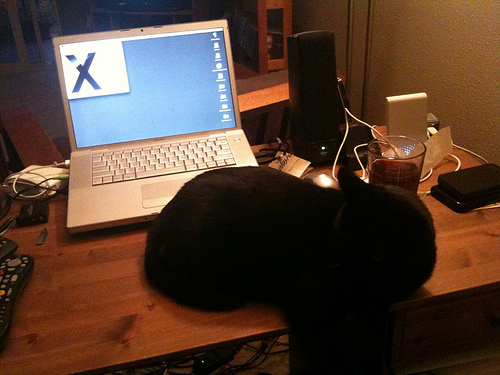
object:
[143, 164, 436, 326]
cat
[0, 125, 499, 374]
desk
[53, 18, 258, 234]
computer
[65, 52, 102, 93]
x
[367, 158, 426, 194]
liquid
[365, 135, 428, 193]
glass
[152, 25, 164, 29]
speaker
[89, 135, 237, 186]
keyboard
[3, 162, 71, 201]
router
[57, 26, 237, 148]
screen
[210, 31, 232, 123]
icons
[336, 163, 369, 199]
ear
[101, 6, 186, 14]
tv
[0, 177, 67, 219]
wires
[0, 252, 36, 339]
remote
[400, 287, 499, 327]
drawers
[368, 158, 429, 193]
half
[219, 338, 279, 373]
cords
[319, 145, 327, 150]
light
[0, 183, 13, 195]
phone